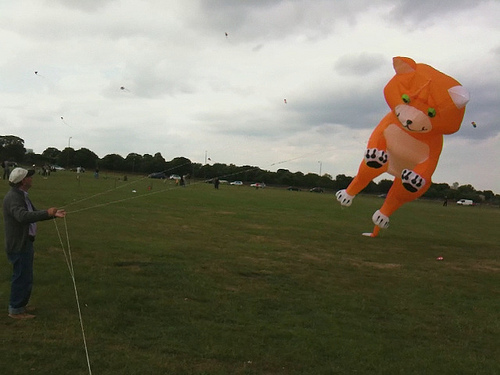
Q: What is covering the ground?
A: Grass.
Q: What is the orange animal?
A: A balloon.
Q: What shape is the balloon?
A: Bear.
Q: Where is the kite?
A: In the air.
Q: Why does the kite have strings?
A: So it does not fly away.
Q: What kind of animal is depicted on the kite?
A: Tiger.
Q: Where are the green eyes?
A: On the kite.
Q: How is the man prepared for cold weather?
A: Coat and hat.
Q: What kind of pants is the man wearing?
A: Blue jeans.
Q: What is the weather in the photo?
A: Overcast.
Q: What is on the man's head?
A: A baseball cap.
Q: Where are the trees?
A: At the edge of the field.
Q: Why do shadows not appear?
A: It is not sunny.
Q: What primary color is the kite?
A: Orange.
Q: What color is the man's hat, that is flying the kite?
A: White.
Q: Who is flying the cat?
A: A man.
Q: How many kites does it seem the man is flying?
A: Three.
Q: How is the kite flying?
A: Wind.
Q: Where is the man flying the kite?
A: A field.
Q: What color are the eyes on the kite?
A: Green.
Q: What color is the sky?
A: Grey and white.